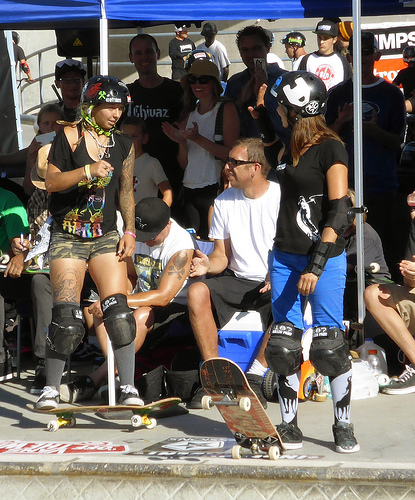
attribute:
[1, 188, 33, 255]
shirt — green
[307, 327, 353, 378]
kneepad — black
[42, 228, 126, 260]
shorts — camo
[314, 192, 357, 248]
pads — elbow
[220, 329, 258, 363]
cooler — blue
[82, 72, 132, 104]
helmet — black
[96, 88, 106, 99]
sticker — red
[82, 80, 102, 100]
sticker — green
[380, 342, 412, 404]
shoe — black and white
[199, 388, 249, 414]
wheels — white 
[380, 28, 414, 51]
mps — white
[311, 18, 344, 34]
cap — black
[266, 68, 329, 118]
helmet — black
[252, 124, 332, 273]
shirt — white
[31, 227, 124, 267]
shorts — camouflage shorts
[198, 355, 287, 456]
skateboard — orange, black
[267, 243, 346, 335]
pants — blue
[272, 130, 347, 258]
shirt — black